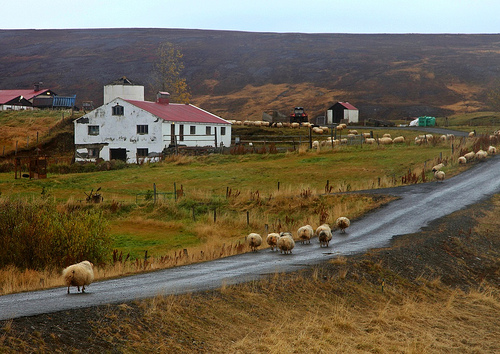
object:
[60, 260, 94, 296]
sheep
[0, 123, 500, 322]
road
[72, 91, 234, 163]
barn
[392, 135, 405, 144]
sheep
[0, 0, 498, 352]
field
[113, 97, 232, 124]
roof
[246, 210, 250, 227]
post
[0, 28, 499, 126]
hill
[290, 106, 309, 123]
tractor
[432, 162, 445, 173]
sheep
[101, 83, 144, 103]
silo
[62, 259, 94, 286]
wool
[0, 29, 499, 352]
grass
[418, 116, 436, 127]
container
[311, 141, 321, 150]
sheep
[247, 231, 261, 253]
sheep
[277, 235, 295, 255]
sheep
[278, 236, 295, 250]
wool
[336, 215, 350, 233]
sheep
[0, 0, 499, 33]
sky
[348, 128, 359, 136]
sheep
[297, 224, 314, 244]
sheep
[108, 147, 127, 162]
doorway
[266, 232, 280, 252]
sheep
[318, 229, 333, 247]
sheep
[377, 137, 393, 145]
sheep